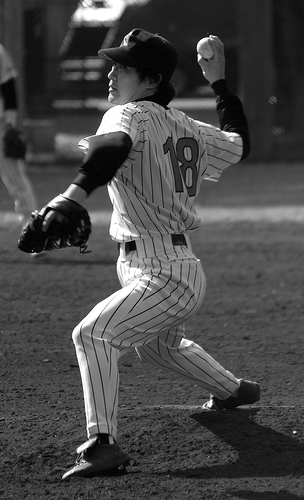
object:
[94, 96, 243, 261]
shirt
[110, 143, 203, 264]
striped shirt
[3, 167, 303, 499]
dirt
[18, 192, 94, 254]
baseball glove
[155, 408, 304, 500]
shadows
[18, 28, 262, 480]
baseball player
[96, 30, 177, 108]
head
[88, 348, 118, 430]
pinstripe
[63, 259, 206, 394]
bent knees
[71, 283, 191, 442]
leg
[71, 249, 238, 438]
pants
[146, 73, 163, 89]
ear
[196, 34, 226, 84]
hand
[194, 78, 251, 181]
arm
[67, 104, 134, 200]
arm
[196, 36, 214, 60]
ball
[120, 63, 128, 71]
eye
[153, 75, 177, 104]
hair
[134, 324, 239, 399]
leg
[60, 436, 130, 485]
foot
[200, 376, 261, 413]
foot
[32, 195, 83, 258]
hand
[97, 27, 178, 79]
cap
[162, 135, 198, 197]
number 18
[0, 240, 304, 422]
field